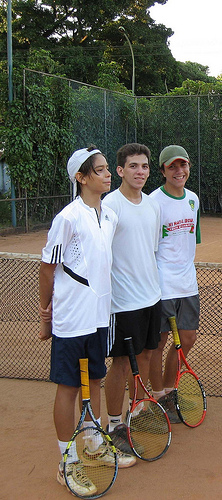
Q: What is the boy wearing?
A: Black and white short sleeve shirt.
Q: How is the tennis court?
A: Dirty.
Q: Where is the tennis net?
A: On the court.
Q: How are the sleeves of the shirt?
A: Black stripes.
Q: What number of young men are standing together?
A: Three.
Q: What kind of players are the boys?
A: Tennis.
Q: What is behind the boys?
A: Net.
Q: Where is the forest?
A: Behind fence.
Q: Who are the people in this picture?
A: Young men.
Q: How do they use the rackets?
A: By swinging.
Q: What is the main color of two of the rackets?
A: Red.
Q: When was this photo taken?
A: Daytime.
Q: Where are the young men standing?
A: Tennis court.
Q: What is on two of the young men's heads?
A: Caps.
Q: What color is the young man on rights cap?
A: Green.